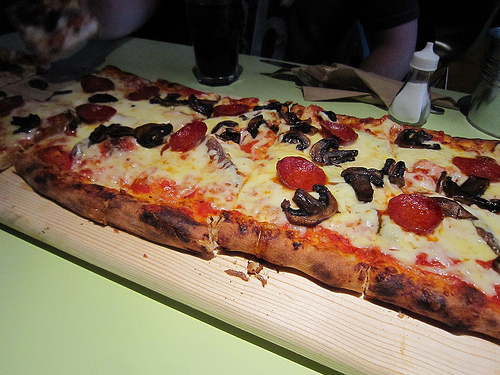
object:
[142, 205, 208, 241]
area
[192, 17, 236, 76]
beverage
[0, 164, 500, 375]
piece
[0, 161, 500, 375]
wood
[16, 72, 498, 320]
toppings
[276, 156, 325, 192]
pepperoni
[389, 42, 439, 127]
container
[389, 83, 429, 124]
sugar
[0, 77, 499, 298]
cheese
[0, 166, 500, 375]
board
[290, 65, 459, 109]
napkin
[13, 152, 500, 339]
crust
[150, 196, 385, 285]
sauce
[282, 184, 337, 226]
mushroom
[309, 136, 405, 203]
mushrooms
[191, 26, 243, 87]
cup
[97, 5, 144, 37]
elbow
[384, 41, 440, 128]
salt shaker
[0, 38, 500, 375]
table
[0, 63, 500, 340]
pizza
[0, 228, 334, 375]
tablecloth